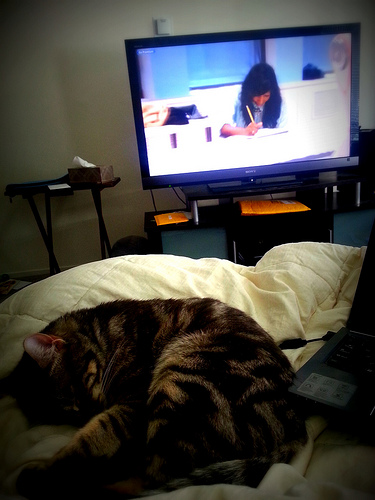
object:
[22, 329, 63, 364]
ear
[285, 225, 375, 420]
laptop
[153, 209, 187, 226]
package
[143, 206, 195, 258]
table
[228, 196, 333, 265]
table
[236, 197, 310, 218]
package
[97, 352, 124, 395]
whisker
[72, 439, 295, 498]
tail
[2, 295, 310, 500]
cat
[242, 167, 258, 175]
label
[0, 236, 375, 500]
blanket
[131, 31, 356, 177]
program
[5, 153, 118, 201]
objects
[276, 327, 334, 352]
charge cord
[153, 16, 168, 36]
thermostat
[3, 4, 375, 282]
wall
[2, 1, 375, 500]
room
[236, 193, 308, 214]
manila envelope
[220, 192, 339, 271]
tv stand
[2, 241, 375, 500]
bed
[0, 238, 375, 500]
sheets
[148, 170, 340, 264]
stand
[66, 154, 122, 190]
tissue box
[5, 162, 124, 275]
table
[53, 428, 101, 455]
paw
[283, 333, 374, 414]
book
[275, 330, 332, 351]
cord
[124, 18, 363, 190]
television